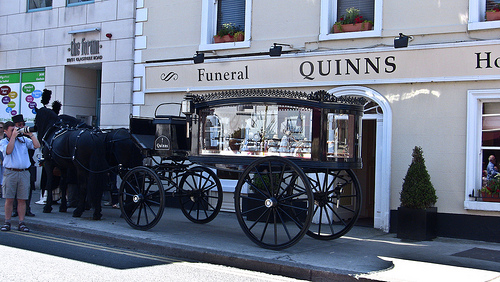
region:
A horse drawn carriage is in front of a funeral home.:
[113, 81, 370, 252]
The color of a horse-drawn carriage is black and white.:
[112, 81, 368, 255]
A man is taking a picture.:
[0, 115, 42, 237]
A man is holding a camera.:
[0, 118, 41, 140]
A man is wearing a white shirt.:
[0, 131, 37, 173]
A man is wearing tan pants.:
[0, 164, 32, 203]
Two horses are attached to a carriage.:
[25, 98, 152, 232]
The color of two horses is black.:
[26, 95, 151, 223]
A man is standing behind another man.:
[0, 108, 38, 222]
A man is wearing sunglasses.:
[12, 115, 27, 128]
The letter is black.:
[196, 63, 206, 83]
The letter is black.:
[202, 68, 216, 83]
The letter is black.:
[212, 67, 223, 84]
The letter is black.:
[222, 68, 231, 80]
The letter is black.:
[291, 56, 318, 82]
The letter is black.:
[315, 55, 334, 79]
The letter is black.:
[329, 53, 344, 80]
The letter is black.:
[341, 54, 362, 76]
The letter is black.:
[361, 52, 382, 76]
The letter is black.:
[383, 53, 398, 78]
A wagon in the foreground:
[113, 75, 368, 255]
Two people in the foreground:
[1, 113, 44, 238]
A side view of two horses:
[28, 94, 143, 231]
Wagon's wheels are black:
[118, 151, 364, 254]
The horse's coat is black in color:
[29, 100, 142, 230]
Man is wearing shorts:
[1, 169, 38, 209]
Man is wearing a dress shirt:
[1, 132, 38, 175]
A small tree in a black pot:
[388, 133, 445, 250]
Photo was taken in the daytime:
[1, 0, 492, 280]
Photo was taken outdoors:
[2, 0, 497, 278]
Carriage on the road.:
[31, 43, 431, 268]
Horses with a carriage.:
[26, 62, 398, 262]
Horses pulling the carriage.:
[21, 43, 449, 238]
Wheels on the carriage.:
[79, 142, 376, 272]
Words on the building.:
[161, 63, 461, 117]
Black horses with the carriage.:
[37, 84, 127, 248]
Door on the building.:
[61, 36, 251, 201]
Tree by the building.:
[391, 142, 468, 254]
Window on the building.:
[191, 1, 311, 67]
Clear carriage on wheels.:
[166, 63, 428, 203]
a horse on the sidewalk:
[27, 27, 205, 280]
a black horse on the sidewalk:
[18, 72, 158, 255]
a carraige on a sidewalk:
[129, 51, 331, 276]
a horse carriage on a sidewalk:
[61, 65, 397, 280]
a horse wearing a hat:
[19, 58, 177, 255]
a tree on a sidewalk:
[366, 133, 444, 279]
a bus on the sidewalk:
[382, 129, 439, 225]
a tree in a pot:
[389, 109, 436, 279]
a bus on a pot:
[377, 113, 442, 280]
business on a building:
[266, 15, 411, 97]